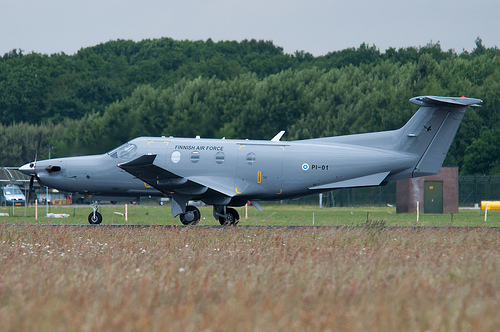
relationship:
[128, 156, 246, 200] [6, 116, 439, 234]
wing of airplane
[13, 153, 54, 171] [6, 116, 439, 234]
propeller on airplane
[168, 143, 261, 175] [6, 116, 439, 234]
windows on airplane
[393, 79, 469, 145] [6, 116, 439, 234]
tail of airplane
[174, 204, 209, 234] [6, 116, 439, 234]
wheel of airplane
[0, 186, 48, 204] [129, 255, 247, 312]
van near field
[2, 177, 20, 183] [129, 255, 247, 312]
building on field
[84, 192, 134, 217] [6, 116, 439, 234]
landing gear on airplane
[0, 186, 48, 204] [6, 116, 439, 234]
van near airplane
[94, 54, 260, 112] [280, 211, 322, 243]
forest near air strip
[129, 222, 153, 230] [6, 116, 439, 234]
fence near airplane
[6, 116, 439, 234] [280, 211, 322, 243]
airplane on air strip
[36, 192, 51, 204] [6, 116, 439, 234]
door on airplane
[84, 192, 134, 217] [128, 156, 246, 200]
landing gear underneath wing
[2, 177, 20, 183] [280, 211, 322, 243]
building near air strip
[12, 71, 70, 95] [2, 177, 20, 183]
tree behind building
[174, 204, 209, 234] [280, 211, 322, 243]
wheel on air strip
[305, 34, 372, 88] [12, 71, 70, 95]
leaves on tree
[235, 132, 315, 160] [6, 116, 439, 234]
stripe on airplane